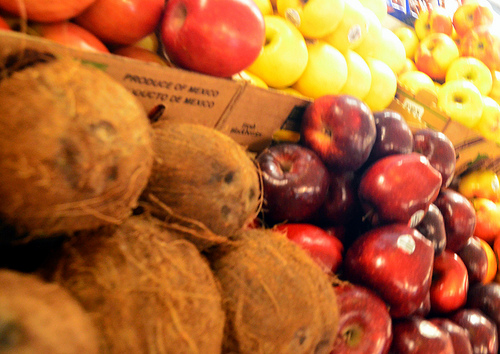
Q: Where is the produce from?
A: Mexico.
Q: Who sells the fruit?
A: Market worker.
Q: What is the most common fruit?
A: Apples.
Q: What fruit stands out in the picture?
A: Coconut.